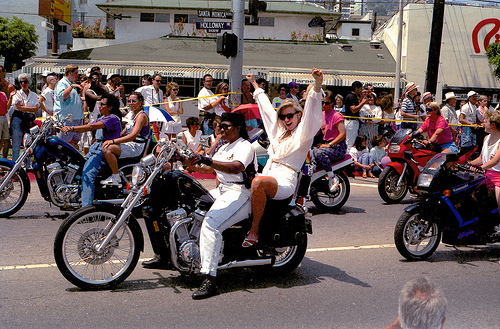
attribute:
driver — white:
[188, 107, 259, 305]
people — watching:
[3, 58, 495, 124]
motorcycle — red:
[372, 125, 481, 203]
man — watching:
[14, 65, 43, 165]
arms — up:
[44, 78, 94, 98]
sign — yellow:
[35, 0, 77, 27]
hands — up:
[237, 70, 344, 93]